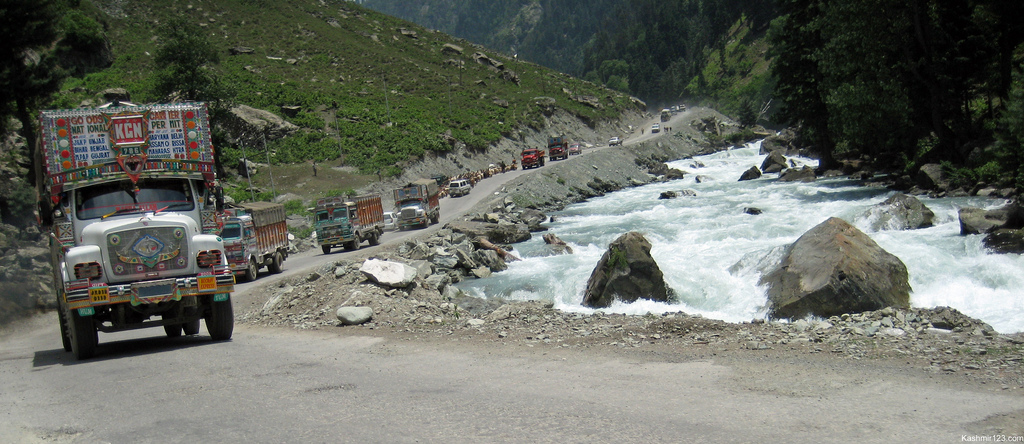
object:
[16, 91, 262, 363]
truck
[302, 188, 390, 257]
cars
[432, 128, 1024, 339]
river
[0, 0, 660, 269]
hill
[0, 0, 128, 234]
trees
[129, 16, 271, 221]
trees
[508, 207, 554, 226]
rocks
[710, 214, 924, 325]
rocks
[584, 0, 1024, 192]
hills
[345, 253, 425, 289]
rock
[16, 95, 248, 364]
car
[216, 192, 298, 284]
car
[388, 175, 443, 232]
car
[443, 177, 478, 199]
car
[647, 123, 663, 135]
car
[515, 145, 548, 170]
car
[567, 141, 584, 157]
car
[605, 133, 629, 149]
car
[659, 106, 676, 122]
car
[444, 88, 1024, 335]
water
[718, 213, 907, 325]
boulder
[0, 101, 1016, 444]
mountain road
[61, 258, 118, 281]
front lights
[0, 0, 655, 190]
grass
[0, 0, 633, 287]
mountainside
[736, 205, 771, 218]
caps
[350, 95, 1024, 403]
river bank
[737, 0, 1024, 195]
tree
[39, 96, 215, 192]
advertisement